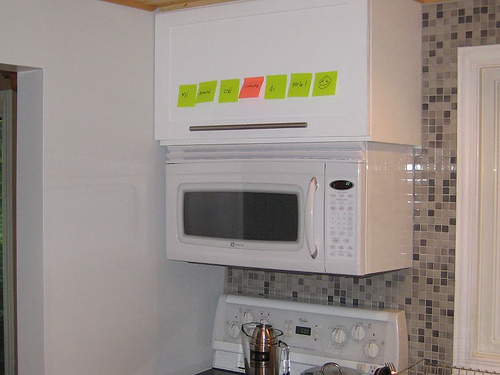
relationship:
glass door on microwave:
[181, 190, 301, 243] [165, 147, 415, 273]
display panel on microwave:
[329, 179, 354, 260] [165, 147, 415, 273]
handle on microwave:
[306, 180, 320, 257] [165, 147, 415, 273]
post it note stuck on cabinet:
[180, 87, 195, 105] [147, 10, 424, 147]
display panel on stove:
[223, 302, 385, 356] [209, 295, 405, 375]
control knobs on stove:
[331, 326, 378, 355] [209, 295, 405, 375]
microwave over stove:
[165, 147, 415, 273] [209, 295, 405, 375]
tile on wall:
[410, 7, 454, 374] [161, 14, 492, 368]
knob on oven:
[229, 322, 241, 338] [209, 295, 405, 375]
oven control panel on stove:
[255, 309, 347, 351] [209, 295, 405, 375]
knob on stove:
[241, 310, 256, 326] [209, 295, 405, 375]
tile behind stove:
[410, 7, 454, 374] [209, 295, 405, 375]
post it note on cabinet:
[290, 72, 310, 97] [147, 10, 424, 147]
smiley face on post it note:
[321, 75, 332, 89] [315, 71, 335, 98]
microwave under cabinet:
[165, 147, 415, 273] [147, 10, 424, 147]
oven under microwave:
[209, 295, 405, 375] [165, 147, 415, 273]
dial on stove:
[330, 328, 345, 345] [209, 295, 405, 375]